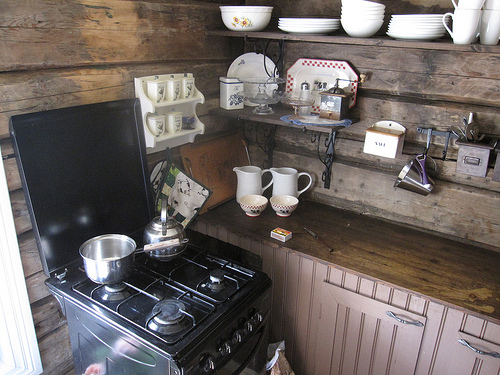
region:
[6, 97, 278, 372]
a black gas stove with an open lid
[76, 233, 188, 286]
a silver sauce pan on a stove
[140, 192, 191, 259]
a silver kettle on a stove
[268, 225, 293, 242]
a box of matches on the counter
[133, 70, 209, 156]
a white shelf hanging on the wall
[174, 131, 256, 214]
a tray on the counter against the wall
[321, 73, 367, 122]
a sifter on a shelf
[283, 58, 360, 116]
a red and white plate on a shelf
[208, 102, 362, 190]
a wooden shelf on the wall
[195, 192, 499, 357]
a wooden counter top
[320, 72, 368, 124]
a manual coffee grinder on a shelf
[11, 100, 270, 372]
a black stove in a kitchen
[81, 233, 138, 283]
a stainless steel pot on a burner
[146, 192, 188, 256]
a kettle on a burner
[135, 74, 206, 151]
white pots on a spice rack on the wall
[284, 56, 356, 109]
a decorative white and red plate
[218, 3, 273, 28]
a bowl with flower printing on a shelf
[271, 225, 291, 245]
a matchbox on a wooden counter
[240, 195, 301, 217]
two tea cups on a wooden counter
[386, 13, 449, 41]
a stack of white plates on a shelf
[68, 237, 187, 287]
a pot on a stove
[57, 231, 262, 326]
a gas cooking stove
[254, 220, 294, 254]
a box of matches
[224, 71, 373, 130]
shelf on a wall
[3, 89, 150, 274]
lid on a stove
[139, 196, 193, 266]
tea kettle on a stove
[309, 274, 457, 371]
cabnet doors below counter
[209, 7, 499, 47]
dishes on a shelf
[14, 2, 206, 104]
wooden logs for wall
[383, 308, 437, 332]
a door handle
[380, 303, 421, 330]
a silver handle on the drawer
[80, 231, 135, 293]
a silver pot on the stovee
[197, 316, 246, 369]
several knobs on front of stove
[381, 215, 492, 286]
a portion of the wooden countertop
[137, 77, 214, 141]
a white rack with several spices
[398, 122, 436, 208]
a large silver cup hanging from rack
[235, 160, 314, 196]
two white pitchers on the countertop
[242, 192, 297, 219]
two colorful bowls on the countertop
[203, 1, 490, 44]
a set of dishes on the top cupboard shelf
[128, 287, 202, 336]
a burner on the top of stove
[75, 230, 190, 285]
The metal pot in on the back burner of stove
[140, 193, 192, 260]
The metal teapot on the back burner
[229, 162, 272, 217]
White pitcher sitting on counter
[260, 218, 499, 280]
A wooden counter top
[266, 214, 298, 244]
Matched on the wooden counter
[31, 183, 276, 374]
A small new gas stove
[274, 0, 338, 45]
White serving plates on the shelf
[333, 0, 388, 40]
White serving bowls on the shelf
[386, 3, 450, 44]
White small serving plates on the shelf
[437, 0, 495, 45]
White coffee cups on the shelf